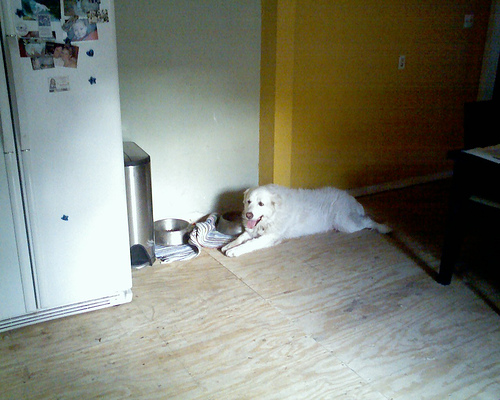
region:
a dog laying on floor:
[204, 140, 411, 273]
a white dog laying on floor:
[218, 150, 428, 302]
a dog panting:
[208, 159, 445, 264]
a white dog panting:
[217, 160, 418, 263]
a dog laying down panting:
[194, 167, 439, 268]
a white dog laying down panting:
[203, 160, 415, 262]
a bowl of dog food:
[187, 175, 278, 239]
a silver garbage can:
[103, 121, 192, 282]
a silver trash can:
[104, 129, 181, 280]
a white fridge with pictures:
[8, 18, 219, 341]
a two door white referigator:
[0, 0, 142, 336]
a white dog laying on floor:
[215, 175, 385, 257]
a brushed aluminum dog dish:
[150, 217, 190, 248]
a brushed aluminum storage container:
[120, 137, 160, 273]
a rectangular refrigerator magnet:
[43, 73, 68, 95]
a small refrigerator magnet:
[56, 208, 72, 222]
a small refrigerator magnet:
[82, 70, 99, 87]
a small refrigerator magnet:
[80, 49, 96, 60]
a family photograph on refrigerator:
[40, 37, 80, 72]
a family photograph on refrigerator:
[57, 14, 99, 44]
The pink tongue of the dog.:
[244, 220, 259, 227]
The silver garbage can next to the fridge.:
[122, 137, 163, 267]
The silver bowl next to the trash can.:
[157, 217, 189, 249]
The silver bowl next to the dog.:
[216, 212, 246, 230]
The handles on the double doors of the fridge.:
[7, 40, 67, 315]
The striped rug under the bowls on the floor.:
[164, 220, 254, 256]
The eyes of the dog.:
[246, 197, 268, 209]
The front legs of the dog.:
[214, 230, 271, 266]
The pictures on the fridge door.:
[12, 8, 108, 95]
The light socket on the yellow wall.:
[396, 52, 411, 72]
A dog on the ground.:
[216, 163, 388, 260]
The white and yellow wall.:
[160, 6, 378, 154]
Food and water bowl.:
[154, 203, 246, 249]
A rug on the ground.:
[151, 240, 211, 271]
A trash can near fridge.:
[120, 125, 166, 273]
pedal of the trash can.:
[133, 249, 149, 274]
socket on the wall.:
[392, 51, 414, 81]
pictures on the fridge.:
[14, 0, 106, 113]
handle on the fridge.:
[0, 32, 42, 302]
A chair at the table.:
[443, 89, 498, 301]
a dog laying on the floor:
[215, 177, 395, 259]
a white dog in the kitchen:
[207, 175, 381, 270]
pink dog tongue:
[235, 207, 276, 239]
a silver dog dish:
[135, 202, 213, 267]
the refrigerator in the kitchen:
[3, 0, 190, 329]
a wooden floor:
[205, 295, 375, 369]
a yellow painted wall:
[287, 15, 407, 143]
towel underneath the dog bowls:
[133, 201, 260, 286]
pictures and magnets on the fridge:
[3, 0, 117, 102]